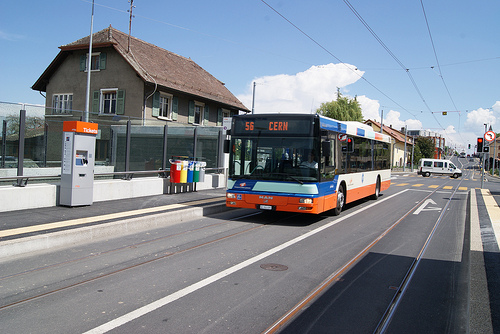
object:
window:
[229, 135, 321, 183]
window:
[373, 139, 391, 170]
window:
[346, 133, 373, 173]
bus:
[224, 112, 394, 217]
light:
[477, 137, 485, 153]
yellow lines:
[442, 185, 453, 189]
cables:
[354, 56, 500, 71]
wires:
[432, 68, 442, 77]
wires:
[419, 0, 479, 138]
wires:
[258, 0, 429, 132]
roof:
[30, 23, 252, 113]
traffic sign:
[484, 131, 496, 142]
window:
[85, 53, 99, 71]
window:
[53, 93, 74, 114]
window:
[100, 88, 118, 115]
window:
[158, 94, 172, 119]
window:
[194, 102, 205, 125]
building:
[30, 22, 254, 166]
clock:
[224, 113, 393, 217]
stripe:
[458, 187, 468, 191]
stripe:
[443, 185, 454, 189]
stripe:
[427, 184, 439, 188]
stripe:
[412, 183, 425, 187]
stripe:
[394, 182, 409, 186]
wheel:
[328, 185, 346, 217]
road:
[0, 156, 500, 333]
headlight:
[227, 193, 236, 198]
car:
[417, 158, 463, 179]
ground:
[0, 155, 500, 332]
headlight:
[299, 198, 313, 204]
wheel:
[368, 176, 381, 200]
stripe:
[251, 181, 319, 195]